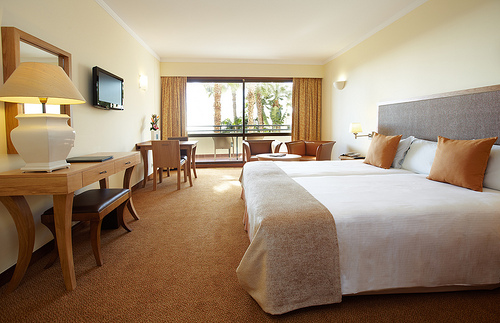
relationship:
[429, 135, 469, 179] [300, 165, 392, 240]
pillow on bed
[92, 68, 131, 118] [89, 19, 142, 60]
tv on wall